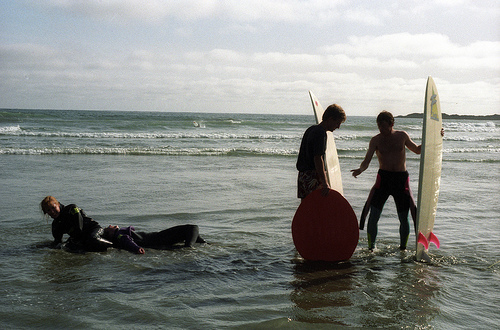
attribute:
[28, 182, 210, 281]
people — lying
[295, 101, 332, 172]
man — standing, looking, carrying, holding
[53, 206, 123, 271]
wetsuit — black, on, worn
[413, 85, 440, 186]
surfboard — pink, white, standing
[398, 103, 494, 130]
land — behind, distant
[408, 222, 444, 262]
fins — pink, neon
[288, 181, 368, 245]
object — egg shaped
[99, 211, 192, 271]
woman — laying, lying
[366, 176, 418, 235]
pants — black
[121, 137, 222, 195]
water — calm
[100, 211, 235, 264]
person — laying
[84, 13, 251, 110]
sky — cloudy, bright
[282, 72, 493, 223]
surfboards — white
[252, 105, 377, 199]
surfers — standing, men, laying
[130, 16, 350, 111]
skies — blue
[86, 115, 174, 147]
waves — small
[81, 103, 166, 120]
ocean — blue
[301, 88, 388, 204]
surboard — white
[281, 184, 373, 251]
board — red, boogie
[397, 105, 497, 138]
mountains — distant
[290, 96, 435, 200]
men — standing